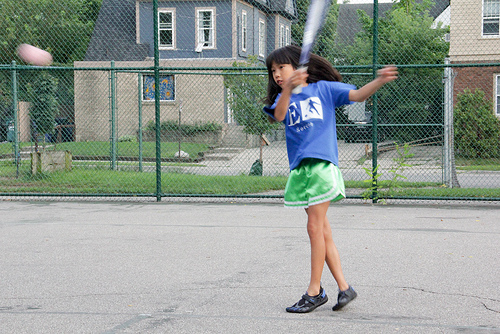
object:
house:
[71, 0, 293, 145]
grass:
[0, 157, 500, 199]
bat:
[288, 0, 328, 94]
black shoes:
[331, 284, 358, 310]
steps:
[208, 126, 248, 159]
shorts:
[283, 159, 346, 210]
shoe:
[286, 286, 329, 313]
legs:
[306, 201, 331, 287]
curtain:
[143, 75, 175, 100]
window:
[158, 8, 174, 47]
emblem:
[288, 97, 323, 134]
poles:
[152, 0, 161, 203]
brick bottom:
[449, 60, 497, 109]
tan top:
[449, 0, 497, 18]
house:
[442, 0, 500, 148]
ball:
[15, 43, 54, 67]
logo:
[285, 97, 323, 132]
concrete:
[1, 197, 498, 330]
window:
[195, 10, 214, 50]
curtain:
[195, 9, 212, 52]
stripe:
[283, 163, 346, 210]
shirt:
[261, 80, 355, 170]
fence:
[2, 0, 500, 206]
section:
[375, 61, 459, 193]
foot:
[285, 293, 328, 313]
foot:
[332, 288, 357, 311]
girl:
[257, 45, 399, 314]